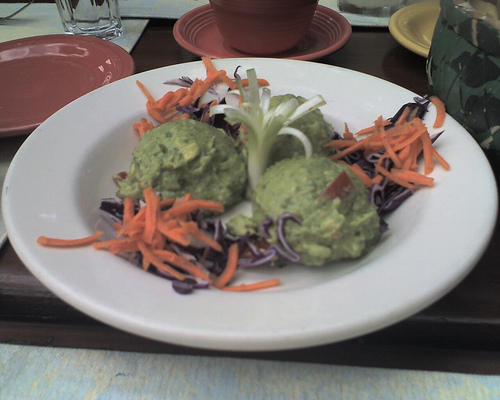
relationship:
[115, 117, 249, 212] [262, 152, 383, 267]
ball of food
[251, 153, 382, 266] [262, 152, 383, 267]
ball of food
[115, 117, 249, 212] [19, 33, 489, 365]
ball in middle of plate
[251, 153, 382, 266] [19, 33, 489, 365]
ball in middle of plate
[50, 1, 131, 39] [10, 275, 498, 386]
glass on table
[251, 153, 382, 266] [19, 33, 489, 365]
ball on plate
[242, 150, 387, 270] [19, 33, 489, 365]
ball on plate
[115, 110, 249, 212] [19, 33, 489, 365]
ball on plate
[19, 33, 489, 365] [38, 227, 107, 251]
plate of veggie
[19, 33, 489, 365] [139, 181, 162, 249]
plate of veggie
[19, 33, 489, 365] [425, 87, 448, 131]
plate of veggie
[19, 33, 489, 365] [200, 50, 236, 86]
plate of veggie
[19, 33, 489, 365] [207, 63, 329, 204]
plate of veggie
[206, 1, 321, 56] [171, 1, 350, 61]
bowl on saucer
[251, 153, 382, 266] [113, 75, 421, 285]
ball mixed with ingredients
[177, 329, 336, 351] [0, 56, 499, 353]
edge of plate